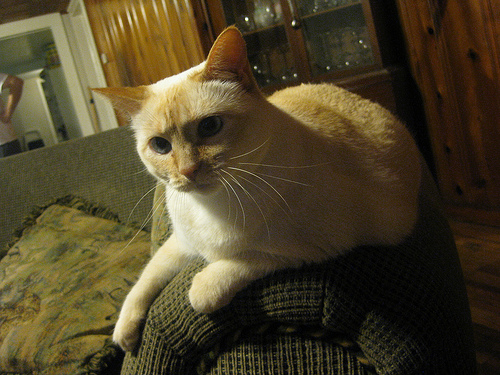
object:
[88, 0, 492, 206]
wall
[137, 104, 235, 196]
face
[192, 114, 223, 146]
green eyes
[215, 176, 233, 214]
white whiskers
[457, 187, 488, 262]
floor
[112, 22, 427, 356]
cat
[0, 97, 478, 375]
chair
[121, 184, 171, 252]
whiskers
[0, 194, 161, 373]
cushon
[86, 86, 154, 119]
ear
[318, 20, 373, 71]
cups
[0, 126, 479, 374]
couch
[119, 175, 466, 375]
sofa arm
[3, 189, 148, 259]
fringe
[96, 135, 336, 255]
whiskers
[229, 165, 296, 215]
whisker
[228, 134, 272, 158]
whisker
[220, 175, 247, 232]
whisker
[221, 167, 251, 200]
whisker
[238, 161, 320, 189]
whisker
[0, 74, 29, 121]
arm/elbow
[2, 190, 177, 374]
pillow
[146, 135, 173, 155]
eye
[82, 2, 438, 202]
cabinet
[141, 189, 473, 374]
sofa arm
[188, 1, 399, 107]
china cabinet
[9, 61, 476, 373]
sofa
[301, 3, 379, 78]
window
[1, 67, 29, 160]
persoin